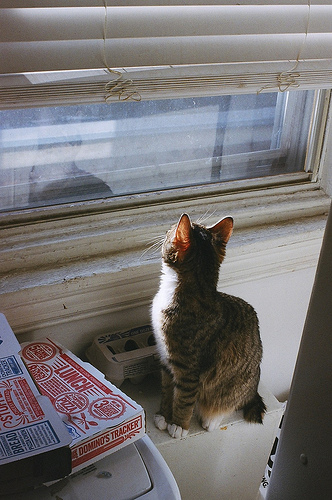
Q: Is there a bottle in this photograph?
A: No, there are no bottles.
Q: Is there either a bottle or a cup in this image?
A: No, there are no bottles or cups.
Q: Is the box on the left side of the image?
A: Yes, the box is on the left of the image.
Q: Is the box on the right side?
A: No, the box is on the left of the image.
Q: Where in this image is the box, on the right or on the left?
A: The box is on the left of the image.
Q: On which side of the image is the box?
A: The box is on the left of the image.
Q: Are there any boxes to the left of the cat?
A: Yes, there is a box to the left of the cat.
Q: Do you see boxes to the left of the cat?
A: Yes, there is a box to the left of the cat.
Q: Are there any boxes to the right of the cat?
A: No, the box is to the left of the cat.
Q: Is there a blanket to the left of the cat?
A: No, there is a box to the left of the cat.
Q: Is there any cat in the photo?
A: Yes, there is a cat.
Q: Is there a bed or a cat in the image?
A: Yes, there is a cat.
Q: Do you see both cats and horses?
A: No, there is a cat but no horses.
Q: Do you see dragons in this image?
A: No, there are no dragons.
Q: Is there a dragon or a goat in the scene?
A: No, there are no dragons or goats.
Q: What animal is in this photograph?
A: The animal is a cat.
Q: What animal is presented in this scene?
A: The animal is a cat.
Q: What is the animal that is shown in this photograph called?
A: The animal is a cat.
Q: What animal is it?
A: The animal is a cat.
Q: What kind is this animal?
A: That is a cat.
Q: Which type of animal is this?
A: That is a cat.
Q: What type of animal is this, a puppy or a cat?
A: That is a cat.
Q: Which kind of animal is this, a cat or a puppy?
A: That is a cat.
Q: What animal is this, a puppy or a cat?
A: This is a cat.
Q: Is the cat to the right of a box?
A: Yes, the cat is to the right of a box.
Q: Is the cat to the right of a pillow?
A: No, the cat is to the right of a box.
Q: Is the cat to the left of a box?
A: No, the cat is to the right of a box.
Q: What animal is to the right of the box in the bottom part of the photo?
A: The animal is a cat.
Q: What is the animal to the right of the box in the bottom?
A: The animal is a cat.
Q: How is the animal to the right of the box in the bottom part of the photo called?
A: The animal is a cat.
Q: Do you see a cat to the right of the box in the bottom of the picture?
A: Yes, there is a cat to the right of the box.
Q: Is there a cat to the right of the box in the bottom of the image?
A: Yes, there is a cat to the right of the box.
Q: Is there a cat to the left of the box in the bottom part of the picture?
A: No, the cat is to the right of the box.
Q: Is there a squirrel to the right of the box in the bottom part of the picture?
A: No, there is a cat to the right of the box.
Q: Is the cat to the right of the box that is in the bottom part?
A: Yes, the cat is to the right of the box.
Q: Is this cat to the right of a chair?
A: No, the cat is to the right of the box.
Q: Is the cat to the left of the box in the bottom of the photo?
A: No, the cat is to the right of the box.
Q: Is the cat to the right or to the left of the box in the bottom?
A: The cat is to the right of the box.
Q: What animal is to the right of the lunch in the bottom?
A: The animal is a cat.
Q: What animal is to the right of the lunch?
A: The animal is a cat.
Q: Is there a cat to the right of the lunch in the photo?
A: Yes, there is a cat to the right of the lunch.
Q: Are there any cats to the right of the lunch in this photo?
A: Yes, there is a cat to the right of the lunch.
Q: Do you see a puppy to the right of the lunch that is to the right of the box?
A: No, there is a cat to the right of the lunch.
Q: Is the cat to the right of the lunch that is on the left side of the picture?
A: Yes, the cat is to the right of the lunch.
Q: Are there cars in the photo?
A: No, there are no cars.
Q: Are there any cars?
A: No, there are no cars.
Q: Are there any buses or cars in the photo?
A: No, there are no cars or buses.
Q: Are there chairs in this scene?
A: No, there are no chairs.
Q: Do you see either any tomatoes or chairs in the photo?
A: No, there are no chairs or tomatoes.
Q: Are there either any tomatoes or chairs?
A: No, there are no chairs or tomatoes.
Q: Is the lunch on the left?
A: Yes, the lunch is on the left of the image.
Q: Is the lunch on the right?
A: No, the lunch is on the left of the image.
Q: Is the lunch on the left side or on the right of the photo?
A: The lunch is on the left of the image.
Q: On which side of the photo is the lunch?
A: The lunch is on the left of the image.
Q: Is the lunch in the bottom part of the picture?
A: Yes, the lunch is in the bottom of the image.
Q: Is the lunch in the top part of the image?
A: No, the lunch is in the bottom of the image.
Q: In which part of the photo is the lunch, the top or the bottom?
A: The lunch is in the bottom of the image.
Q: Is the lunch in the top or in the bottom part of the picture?
A: The lunch is in the bottom of the image.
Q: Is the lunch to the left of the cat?
A: Yes, the lunch is to the left of the cat.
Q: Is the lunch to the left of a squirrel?
A: No, the lunch is to the left of the cat.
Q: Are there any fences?
A: No, there are no fences.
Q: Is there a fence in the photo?
A: No, there are no fences.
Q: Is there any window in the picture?
A: Yes, there is a window.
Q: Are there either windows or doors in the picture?
A: Yes, there is a window.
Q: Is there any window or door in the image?
A: Yes, there is a window.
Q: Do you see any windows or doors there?
A: Yes, there is a window.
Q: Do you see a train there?
A: No, there are no trains.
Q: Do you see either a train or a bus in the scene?
A: No, there are no trains or buses.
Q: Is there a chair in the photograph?
A: No, there are no chairs.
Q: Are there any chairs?
A: No, there are no chairs.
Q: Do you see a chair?
A: No, there are no chairs.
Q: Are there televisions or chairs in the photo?
A: No, there are no chairs or televisions.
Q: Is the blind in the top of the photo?
A: Yes, the blind is in the top of the image.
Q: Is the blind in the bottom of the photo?
A: No, the blind is in the top of the image.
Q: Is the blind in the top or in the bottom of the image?
A: The blind is in the top of the image.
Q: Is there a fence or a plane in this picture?
A: No, there are no fences or airplanes.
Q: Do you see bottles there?
A: No, there are no bottles.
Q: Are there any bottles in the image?
A: No, there are no bottles.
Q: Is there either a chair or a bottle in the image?
A: No, there are no bottles or chairs.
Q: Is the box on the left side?
A: Yes, the box is on the left of the image.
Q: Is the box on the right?
A: No, the box is on the left of the image.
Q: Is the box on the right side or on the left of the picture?
A: The box is on the left of the image.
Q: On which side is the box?
A: The box is on the left of the image.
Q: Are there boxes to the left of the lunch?
A: Yes, there is a box to the left of the lunch.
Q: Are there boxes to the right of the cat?
A: No, the box is to the left of the cat.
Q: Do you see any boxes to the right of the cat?
A: No, the box is to the left of the cat.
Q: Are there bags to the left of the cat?
A: No, there is a box to the left of the cat.